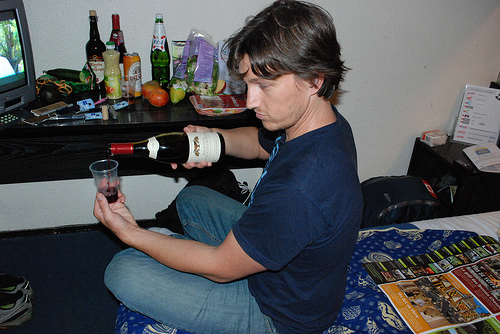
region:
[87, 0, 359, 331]
Man holding a bottle of wine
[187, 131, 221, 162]
Label on the wine bottle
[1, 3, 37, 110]
TV on the table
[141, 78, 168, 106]
Apples on the table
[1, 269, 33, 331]
Pair of shoes on the floor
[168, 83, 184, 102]
A pear on the table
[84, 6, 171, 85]
Glass bottles on the table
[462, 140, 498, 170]
A brochure on the night stand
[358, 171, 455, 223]
Backpack on the floor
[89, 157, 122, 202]
Cup in the man's hand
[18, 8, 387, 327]
man sitting on floor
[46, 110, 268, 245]
man pouring wine into cup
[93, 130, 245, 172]
man holding wine bottle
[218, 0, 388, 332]
man wearing blue shirt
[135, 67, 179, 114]
two apples on table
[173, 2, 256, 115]
salad in a bag on table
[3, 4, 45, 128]
small tv on table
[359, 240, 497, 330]
paper on bed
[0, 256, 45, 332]
sneakers on the floor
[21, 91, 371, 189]
black table in room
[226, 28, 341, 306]
this is a man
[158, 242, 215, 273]
the man has a light skin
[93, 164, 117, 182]
this is a glass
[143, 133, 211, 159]
this is a bottle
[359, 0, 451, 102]
this is a wall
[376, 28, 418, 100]
the wall is white in color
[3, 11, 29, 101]
this is a television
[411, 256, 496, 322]
this is a magazine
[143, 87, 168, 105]
this is an apple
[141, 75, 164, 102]
the apples are two in number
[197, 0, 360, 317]
this is a man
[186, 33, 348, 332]
then man is sitted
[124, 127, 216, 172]
this is a bottle of wine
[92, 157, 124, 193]
the hand is holding a cup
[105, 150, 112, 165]
the wine is flowing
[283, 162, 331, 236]
te t shirt is blue in color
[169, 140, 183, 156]
the bottle is black in color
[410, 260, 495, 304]
this is a magazine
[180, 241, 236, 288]
the elbow is on the lap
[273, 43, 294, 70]
the hair is short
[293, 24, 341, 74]
hair of a man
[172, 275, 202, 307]
part of a trouser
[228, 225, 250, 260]
edge of a sleeve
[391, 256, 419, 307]
part of a calendar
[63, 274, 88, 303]
part of a floor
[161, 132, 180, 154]
part of a bottle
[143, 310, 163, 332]
edge of a shoe